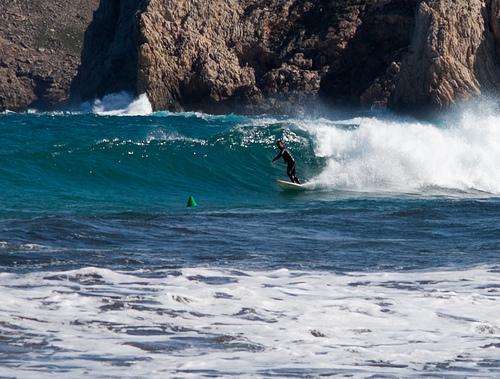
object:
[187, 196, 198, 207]
cone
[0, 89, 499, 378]
water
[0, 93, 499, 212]
wave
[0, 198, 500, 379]
surface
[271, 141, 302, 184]
man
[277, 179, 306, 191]
surfboard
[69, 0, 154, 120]
shadow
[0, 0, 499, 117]
formation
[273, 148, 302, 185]
wetsuit